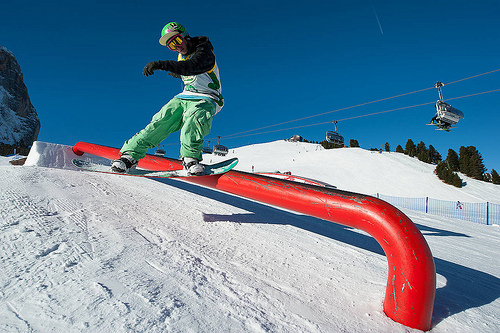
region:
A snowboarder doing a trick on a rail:
[62, 11, 240, 201]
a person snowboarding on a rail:
[75, 134, 315, 239]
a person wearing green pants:
[134, 71, 281, 181]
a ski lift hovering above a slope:
[318, 89, 498, 140]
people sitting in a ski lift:
[414, 94, 487, 169]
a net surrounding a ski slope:
[391, 189, 496, 259]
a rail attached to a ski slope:
[83, 134, 446, 327]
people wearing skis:
[424, 107, 464, 149]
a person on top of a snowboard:
[102, 157, 252, 215]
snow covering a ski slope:
[136, 195, 256, 307]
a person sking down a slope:
[446, 190, 483, 242]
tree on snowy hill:
[433, 160, 468, 187]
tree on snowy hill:
[487, 168, 498, 185]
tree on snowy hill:
[471, 144, 486, 176]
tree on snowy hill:
[459, 145, 470, 172]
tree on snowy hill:
[444, 145, 458, 163]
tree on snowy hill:
[425, 140, 440, 160]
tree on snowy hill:
[402, 135, 420, 153]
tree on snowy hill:
[391, 142, 405, 152]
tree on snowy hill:
[380, 138, 392, 151]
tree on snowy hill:
[480, 171, 489, 181]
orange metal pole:
[64, 135, 442, 330]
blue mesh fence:
[371, 190, 497, 232]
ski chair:
[422, 77, 471, 140]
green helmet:
[149, 18, 196, 58]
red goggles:
[163, 27, 195, 57]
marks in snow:
[20, 213, 181, 328]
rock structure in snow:
[2, 45, 42, 162]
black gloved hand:
[138, 57, 163, 82]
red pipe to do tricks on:
[257, 179, 444, 331]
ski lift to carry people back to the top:
[367, 85, 482, 141]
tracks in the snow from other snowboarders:
[23, 190, 235, 324]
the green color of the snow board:
[177, 158, 263, 183]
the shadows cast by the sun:
[205, 197, 490, 327]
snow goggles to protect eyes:
[156, 38, 203, 54]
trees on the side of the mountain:
[392, 138, 484, 193]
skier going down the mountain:
[431, 200, 471, 222]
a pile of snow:
[27, 133, 88, 179]